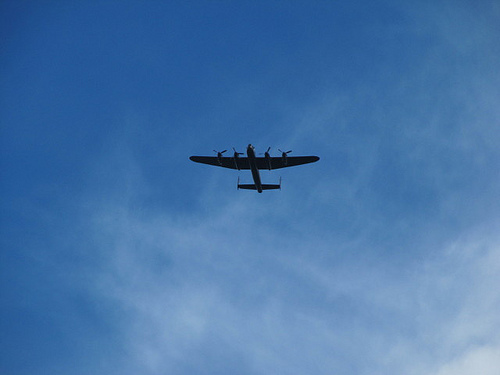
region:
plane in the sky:
[175, 134, 333, 205]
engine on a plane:
[211, 145, 230, 169]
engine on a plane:
[228, 143, 247, 175]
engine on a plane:
[258, 140, 277, 175]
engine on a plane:
[277, 144, 293, 172]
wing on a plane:
[256, 143, 323, 179]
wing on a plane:
[185, 143, 249, 176]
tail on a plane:
[230, 170, 287, 197]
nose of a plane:
[241, 138, 259, 157]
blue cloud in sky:
[105, 200, 160, 255]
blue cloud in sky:
[128, 184, 170, 226]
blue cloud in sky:
[41, 173, 92, 208]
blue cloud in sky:
[64, 174, 108, 214]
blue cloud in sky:
[185, 178, 256, 220]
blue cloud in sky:
[423, 171, 479, 222]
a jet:
[177, 142, 330, 192]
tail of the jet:
[227, 175, 282, 195]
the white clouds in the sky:
[105, 220, 395, 340]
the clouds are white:
[107, 220, 320, 338]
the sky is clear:
[27, 45, 138, 101]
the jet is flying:
[163, 145, 319, 191]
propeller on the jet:
[280, 145, 290, 158]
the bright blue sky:
[180, 25, 266, 81]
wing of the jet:
[187, 148, 211, 173]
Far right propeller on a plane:
[213, 147, 223, 157]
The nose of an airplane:
[245, 141, 255, 152]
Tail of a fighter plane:
[235, 177, 282, 188]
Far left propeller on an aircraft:
[275, 146, 287, 156]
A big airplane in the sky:
[189, 143, 324, 191]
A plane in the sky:
[187, 145, 319, 193]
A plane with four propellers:
[185, 145, 320, 192]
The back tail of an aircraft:
[236, 178, 281, 193]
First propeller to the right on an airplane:
[232, 145, 242, 160]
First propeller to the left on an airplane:
[259, 146, 273, 158]